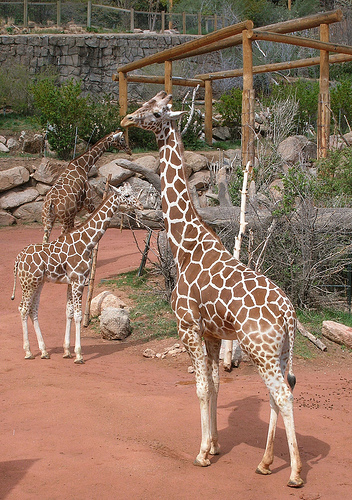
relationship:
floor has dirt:
[2, 225, 350, 498] [0, 353, 351, 466]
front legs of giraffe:
[170, 281, 222, 467] [93, 106, 267, 418]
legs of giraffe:
[254, 350, 303, 489] [119, 89, 330, 493]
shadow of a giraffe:
[88, 328, 134, 433] [50, 32, 276, 302]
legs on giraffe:
[173, 325, 235, 473] [119, 89, 330, 493]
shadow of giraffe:
[213, 388, 335, 485] [119, 89, 330, 493]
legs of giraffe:
[173, 325, 235, 473] [119, 89, 330, 493]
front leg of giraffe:
[176, 323, 213, 467] [119, 89, 330, 493]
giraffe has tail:
[119, 89, 330, 493] [283, 306, 306, 391]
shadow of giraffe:
[213, 388, 335, 485] [114, 83, 317, 476]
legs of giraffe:
[254, 350, 303, 489] [117, 91, 304, 487]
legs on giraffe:
[173, 325, 235, 473] [114, 83, 317, 476]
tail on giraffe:
[279, 297, 305, 393] [117, 91, 304, 487]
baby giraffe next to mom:
[8, 176, 144, 373] [113, 85, 324, 494]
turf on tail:
[287, 371, 296, 388] [242, 267, 325, 429]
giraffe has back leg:
[119, 89, 330, 493] [255, 331, 291, 477]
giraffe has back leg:
[119, 89, 330, 493] [233, 318, 304, 486]